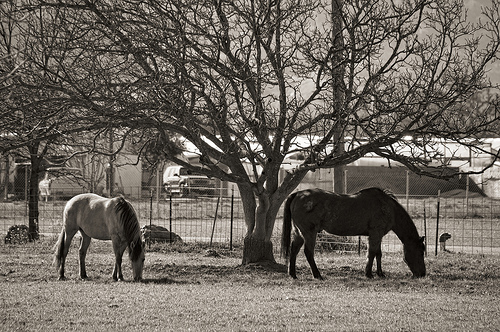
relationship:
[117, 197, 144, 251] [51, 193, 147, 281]
mane on horse